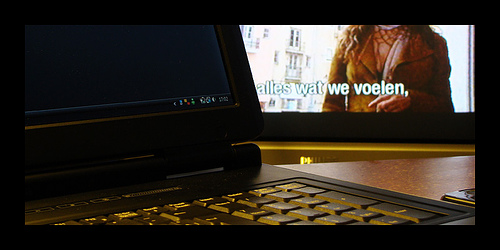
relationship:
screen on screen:
[9, 12, 224, 107] [0, 23, 238, 117]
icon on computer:
[172, 100, 177, 105] [3, 11, 476, 223]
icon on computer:
[179, 100, 182, 107] [3, 11, 476, 223]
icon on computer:
[184, 98, 189, 105] [3, 11, 476, 223]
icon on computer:
[191, 98, 196, 105] [3, 11, 476, 223]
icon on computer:
[200, 97, 205, 103] [3, 11, 476, 223]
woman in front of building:
[321, 22, 453, 114] [248, 29, 322, 103]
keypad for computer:
[25, 165, 480, 225] [3, 11, 476, 223]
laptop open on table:
[24, 24, 477, 227] [273, 129, 491, 196]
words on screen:
[254, 80, 404, 96] [239, 23, 476, 113]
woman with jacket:
[321, 22, 457, 117] [321, 27, 452, 114]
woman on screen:
[321, 22, 457, 117] [239, 23, 476, 116]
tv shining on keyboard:
[223, 22, 486, 143] [188, 175, 373, 217]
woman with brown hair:
[321, 22, 457, 117] [330, 25, 440, 58]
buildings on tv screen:
[243, 24, 347, 116] [227, 17, 472, 135]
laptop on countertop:
[24, 24, 477, 227] [273, 156, 474, 208]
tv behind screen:
[223, 22, 486, 143] [23, 24, 248, 125]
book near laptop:
[436, 182, 479, 214] [4, 5, 472, 222]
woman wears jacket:
[321, 22, 457, 117] [321, 27, 452, 114]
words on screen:
[254, 75, 439, 103] [242, 21, 471, 110]